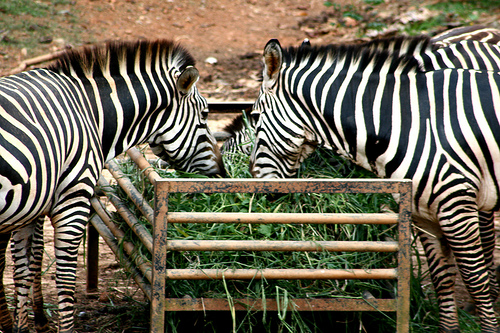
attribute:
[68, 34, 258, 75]
maine — black and white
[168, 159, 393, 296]
grass — short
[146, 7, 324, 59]
gravel — red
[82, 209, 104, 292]
legs — wooden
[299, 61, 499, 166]
stripes — black and white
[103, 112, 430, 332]
grass — green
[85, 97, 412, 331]
crate — metal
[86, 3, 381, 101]
dirt ground — brown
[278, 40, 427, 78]
mane — thick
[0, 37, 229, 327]
zebra — striped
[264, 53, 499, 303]
zebra — striped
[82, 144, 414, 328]
fence — wooden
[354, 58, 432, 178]
stripes — black, white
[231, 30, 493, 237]
zebra — white, black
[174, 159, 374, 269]
plants — green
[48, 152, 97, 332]
leg — striped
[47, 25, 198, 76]
mane — black and white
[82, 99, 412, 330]
feeding crate — old, worn, brown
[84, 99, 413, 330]
feeding square — metal